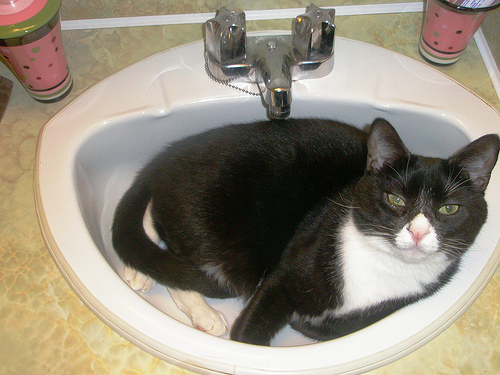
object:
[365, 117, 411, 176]
ear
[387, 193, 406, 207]
eye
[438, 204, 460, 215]
eye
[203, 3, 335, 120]
faucet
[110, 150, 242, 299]
tail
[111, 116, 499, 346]
cat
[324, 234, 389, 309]
fur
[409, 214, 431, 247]
nose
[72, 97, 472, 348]
sink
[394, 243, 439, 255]
mouth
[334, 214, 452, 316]
white patch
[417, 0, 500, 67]
cup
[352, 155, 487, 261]
eyelid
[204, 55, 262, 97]
chain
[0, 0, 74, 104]
cup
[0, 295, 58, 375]
counter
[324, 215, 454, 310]
chest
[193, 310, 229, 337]
paws